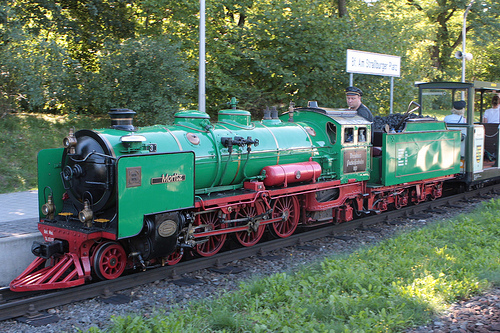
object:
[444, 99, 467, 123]
people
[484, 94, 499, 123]
people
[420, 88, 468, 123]
window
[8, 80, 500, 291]
car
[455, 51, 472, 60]
speakers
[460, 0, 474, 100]
pole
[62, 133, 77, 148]
headlight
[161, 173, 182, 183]
word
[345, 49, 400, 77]
sign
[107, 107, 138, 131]
smoke stacks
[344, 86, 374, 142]
man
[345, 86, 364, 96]
hat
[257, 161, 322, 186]
cylinder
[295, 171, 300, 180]
gauge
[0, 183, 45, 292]
road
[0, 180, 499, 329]
tracks